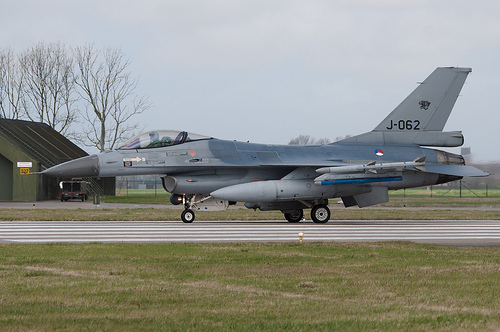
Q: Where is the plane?
A: On runway.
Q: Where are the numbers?
A: On the plane.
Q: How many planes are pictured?
A: One.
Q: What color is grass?
A: Green.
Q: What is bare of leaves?
A: Trees.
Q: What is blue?
A: Sky.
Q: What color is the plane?
A: Gray.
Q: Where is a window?
A: On the plane.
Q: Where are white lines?
A: On the tarmac.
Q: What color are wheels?
A: Black and white.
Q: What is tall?
A: Trees.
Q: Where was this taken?
A: Airport.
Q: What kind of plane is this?
A: Jet.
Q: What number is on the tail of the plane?
A: J062.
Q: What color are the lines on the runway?
A: White.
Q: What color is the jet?
A: Gray.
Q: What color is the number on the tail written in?
A: Black.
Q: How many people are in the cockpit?
A: 1.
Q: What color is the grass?
A: Green.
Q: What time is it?
A: Afternoon.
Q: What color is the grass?
A: Green and brown.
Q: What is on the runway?
A: Plane.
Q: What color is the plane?
A: Grey.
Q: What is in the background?
A: Bare trees.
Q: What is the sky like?
A: Overcast.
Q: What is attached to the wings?
A: Missiles.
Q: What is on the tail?
A: J-062.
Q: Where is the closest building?
A: On the far left.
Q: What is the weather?
A: Overcast.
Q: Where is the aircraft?
A: On a runway.